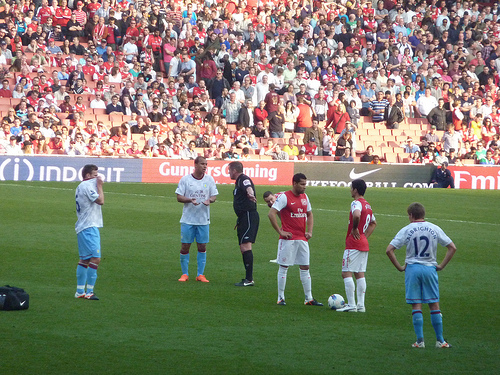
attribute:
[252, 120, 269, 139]
spectator — watching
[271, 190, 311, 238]
jersey — red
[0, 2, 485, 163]
spectators — watching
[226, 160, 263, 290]
referee — wearing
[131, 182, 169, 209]
line — long, white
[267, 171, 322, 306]
player — wearing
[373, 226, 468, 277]
jersey — soccer, white, player's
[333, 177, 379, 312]
player — soccer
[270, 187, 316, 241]
shirt — white, red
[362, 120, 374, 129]
seat — empty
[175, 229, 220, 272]
shorts — blue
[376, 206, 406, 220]
line — white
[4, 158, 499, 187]
sign — red, white, long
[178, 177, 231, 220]
jersey — soccer, player's, white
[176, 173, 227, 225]
shorts — blue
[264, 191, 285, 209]
player — soccer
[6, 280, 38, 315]
bag — black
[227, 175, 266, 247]
jersey — white, soccer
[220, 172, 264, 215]
shirt — black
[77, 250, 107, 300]
sock — long, blue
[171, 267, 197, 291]
shoe — orange